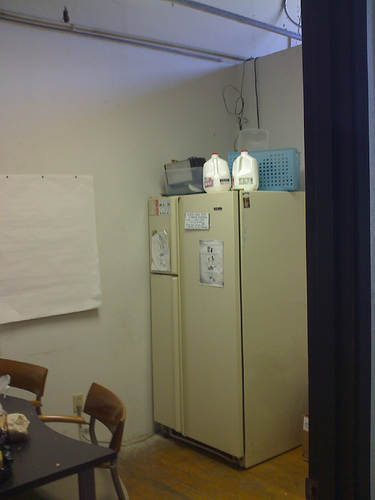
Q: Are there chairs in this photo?
A: Yes, there is a chair.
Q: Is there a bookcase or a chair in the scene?
A: Yes, there is a chair.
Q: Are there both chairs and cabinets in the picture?
A: No, there is a chair but no cabinets.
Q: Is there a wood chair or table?
A: Yes, there is a wood chair.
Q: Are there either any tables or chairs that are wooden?
A: Yes, the chair is wooden.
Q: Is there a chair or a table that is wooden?
A: Yes, the chair is wooden.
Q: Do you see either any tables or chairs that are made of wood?
A: Yes, the chair is made of wood.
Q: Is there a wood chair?
A: Yes, there is a chair that is made of wood.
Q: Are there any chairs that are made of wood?
A: Yes, there is a chair that is made of wood.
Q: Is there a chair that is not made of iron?
A: Yes, there is a chair that is made of wood.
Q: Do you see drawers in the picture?
A: No, there are no drawers.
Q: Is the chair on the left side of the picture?
A: Yes, the chair is on the left of the image.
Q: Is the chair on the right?
A: No, the chair is on the left of the image.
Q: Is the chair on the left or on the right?
A: The chair is on the left of the image.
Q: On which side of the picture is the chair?
A: The chair is on the left of the image.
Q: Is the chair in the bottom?
A: Yes, the chair is in the bottom of the image.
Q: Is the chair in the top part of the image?
A: No, the chair is in the bottom of the image.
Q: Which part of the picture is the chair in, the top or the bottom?
A: The chair is in the bottom of the image.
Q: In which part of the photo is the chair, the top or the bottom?
A: The chair is in the bottom of the image.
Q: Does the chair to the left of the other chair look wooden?
A: Yes, the chair is wooden.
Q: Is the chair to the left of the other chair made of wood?
A: Yes, the chair is made of wood.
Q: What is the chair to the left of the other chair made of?
A: The chair is made of wood.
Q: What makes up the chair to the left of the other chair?
A: The chair is made of wood.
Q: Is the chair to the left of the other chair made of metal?
A: No, the chair is made of wood.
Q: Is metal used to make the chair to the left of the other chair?
A: No, the chair is made of wood.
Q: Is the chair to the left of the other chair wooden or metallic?
A: The chair is wooden.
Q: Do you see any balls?
A: No, there are no balls.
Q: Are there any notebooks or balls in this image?
A: No, there are no balls or notebooks.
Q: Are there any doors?
A: Yes, there is a door.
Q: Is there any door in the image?
A: Yes, there is a door.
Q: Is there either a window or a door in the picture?
A: Yes, there is a door.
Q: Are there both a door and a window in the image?
A: No, there is a door but no windows.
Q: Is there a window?
A: No, there are no windows.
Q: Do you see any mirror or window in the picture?
A: No, there are no windows or mirrors.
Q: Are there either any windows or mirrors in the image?
A: No, there are no windows or mirrors.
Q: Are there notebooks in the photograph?
A: No, there are no notebooks.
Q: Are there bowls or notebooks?
A: No, there are no notebooks or bowls.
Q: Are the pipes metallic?
A: Yes, the pipes are metallic.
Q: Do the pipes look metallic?
A: Yes, the pipes are metallic.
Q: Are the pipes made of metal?
A: Yes, the pipes are made of metal.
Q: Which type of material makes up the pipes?
A: The pipes are made of metal.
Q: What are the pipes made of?
A: The pipes are made of metal.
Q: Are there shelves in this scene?
A: No, there are no shelves.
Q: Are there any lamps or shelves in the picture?
A: No, there are no shelves or lamps.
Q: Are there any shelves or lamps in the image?
A: No, there are no shelves or lamps.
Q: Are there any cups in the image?
A: No, there are no cups.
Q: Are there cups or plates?
A: No, there are no cups or plates.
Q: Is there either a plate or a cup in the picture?
A: No, there are no cups or plates.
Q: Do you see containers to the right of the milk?
A: Yes, there is a container to the right of the milk.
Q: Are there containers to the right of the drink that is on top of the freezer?
A: Yes, there is a container to the right of the milk.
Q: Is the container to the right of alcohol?
A: No, the container is to the right of the milk.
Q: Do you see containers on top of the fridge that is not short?
A: Yes, there is a container on top of the fridge.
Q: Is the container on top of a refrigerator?
A: Yes, the container is on top of a refrigerator.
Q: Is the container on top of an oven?
A: No, the container is on top of a refrigerator.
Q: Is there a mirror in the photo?
A: No, there are no mirrors.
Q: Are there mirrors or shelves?
A: No, there are no mirrors or shelves.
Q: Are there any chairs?
A: Yes, there is a chair.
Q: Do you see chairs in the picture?
A: Yes, there is a chair.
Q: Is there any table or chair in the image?
A: Yes, there is a chair.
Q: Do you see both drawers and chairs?
A: No, there is a chair but no drawers.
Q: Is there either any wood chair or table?
A: Yes, there is a wood chair.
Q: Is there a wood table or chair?
A: Yes, there is a wood chair.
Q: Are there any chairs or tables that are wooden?
A: Yes, the chair is wooden.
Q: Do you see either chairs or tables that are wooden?
A: Yes, the chair is wooden.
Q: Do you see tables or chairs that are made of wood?
A: Yes, the chair is made of wood.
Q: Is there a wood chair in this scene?
A: Yes, there is a wood chair.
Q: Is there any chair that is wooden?
A: Yes, there is a chair that is wooden.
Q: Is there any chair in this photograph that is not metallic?
A: Yes, there is a wooden chair.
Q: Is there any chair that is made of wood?
A: Yes, there is a chair that is made of wood.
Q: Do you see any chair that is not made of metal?
A: Yes, there is a chair that is made of wood.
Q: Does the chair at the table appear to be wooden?
A: Yes, the chair is wooden.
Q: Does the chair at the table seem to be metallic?
A: No, the chair is wooden.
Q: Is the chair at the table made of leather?
A: No, the chair is made of wood.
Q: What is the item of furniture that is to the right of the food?
A: The piece of furniture is a chair.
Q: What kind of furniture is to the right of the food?
A: The piece of furniture is a chair.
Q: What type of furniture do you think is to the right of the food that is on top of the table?
A: The piece of furniture is a chair.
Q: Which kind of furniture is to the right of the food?
A: The piece of furniture is a chair.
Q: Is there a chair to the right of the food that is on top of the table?
A: Yes, there is a chair to the right of the food.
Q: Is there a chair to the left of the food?
A: No, the chair is to the right of the food.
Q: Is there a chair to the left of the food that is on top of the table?
A: No, the chair is to the right of the food.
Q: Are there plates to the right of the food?
A: No, there is a chair to the right of the food.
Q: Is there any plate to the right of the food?
A: No, there is a chair to the right of the food.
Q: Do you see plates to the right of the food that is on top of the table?
A: No, there is a chair to the right of the food.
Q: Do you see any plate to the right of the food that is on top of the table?
A: No, there is a chair to the right of the food.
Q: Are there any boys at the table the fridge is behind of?
A: No, there is a chair at the table.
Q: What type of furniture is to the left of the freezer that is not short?
A: The piece of furniture is a chair.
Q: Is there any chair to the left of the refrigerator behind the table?
A: Yes, there is a chair to the left of the refrigerator.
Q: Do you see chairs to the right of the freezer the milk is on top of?
A: No, the chair is to the left of the refrigerator.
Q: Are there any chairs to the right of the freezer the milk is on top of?
A: No, the chair is to the left of the refrigerator.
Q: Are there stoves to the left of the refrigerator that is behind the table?
A: No, there is a chair to the left of the freezer.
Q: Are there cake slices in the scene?
A: No, there are no cake slices.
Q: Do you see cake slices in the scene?
A: No, there are no cake slices.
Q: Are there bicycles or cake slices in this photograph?
A: No, there are no cake slices or bicycles.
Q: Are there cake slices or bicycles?
A: No, there are no cake slices or bicycles.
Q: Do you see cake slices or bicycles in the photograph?
A: No, there are no cake slices or bicycles.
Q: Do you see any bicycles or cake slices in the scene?
A: No, there are no cake slices or bicycles.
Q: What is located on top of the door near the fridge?
A: The paper is on top of the door.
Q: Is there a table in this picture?
A: Yes, there is a table.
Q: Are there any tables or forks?
A: Yes, there is a table.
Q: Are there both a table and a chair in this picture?
A: Yes, there are both a table and a chair.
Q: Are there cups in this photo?
A: No, there are no cups.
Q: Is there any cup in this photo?
A: No, there are no cups.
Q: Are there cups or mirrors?
A: No, there are no cups or mirrors.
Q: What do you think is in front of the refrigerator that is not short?
A: The table is in front of the fridge.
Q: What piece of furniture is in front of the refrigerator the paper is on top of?
A: The piece of furniture is a table.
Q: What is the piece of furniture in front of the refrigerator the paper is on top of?
A: The piece of furniture is a table.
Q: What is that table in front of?
A: The table is in front of the fridge.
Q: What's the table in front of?
A: The table is in front of the fridge.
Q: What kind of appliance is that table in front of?
A: The table is in front of the refrigerator.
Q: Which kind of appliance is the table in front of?
A: The table is in front of the refrigerator.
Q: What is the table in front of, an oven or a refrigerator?
A: The table is in front of a refrigerator.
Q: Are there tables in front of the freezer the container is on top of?
A: Yes, there is a table in front of the freezer.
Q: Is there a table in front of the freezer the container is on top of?
A: Yes, there is a table in front of the freezer.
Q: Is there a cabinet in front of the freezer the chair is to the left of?
A: No, there is a table in front of the refrigerator.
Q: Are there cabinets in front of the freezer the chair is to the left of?
A: No, there is a table in front of the refrigerator.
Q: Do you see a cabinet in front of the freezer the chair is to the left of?
A: No, there is a table in front of the refrigerator.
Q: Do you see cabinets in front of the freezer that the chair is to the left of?
A: No, there is a table in front of the refrigerator.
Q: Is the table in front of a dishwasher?
A: No, the table is in front of a refrigerator.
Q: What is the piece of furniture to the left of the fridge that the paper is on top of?
A: The piece of furniture is a table.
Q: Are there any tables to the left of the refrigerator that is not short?
A: Yes, there is a table to the left of the refrigerator.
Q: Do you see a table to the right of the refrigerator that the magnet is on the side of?
A: No, the table is to the left of the fridge.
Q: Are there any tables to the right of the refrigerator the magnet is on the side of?
A: No, the table is to the left of the fridge.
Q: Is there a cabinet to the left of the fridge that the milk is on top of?
A: No, there is a table to the left of the freezer.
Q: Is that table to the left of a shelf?
A: No, the table is to the left of the fridge.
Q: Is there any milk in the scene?
A: Yes, there is milk.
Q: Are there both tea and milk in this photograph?
A: No, there is milk but no tea.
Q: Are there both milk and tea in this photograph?
A: No, there is milk but no tea.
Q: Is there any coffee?
A: No, there is no coffee.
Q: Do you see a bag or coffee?
A: No, there are no coffee or bags.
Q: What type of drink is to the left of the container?
A: The drink is milk.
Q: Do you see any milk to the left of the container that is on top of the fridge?
A: Yes, there is milk to the left of the container.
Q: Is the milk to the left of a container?
A: Yes, the milk is to the left of a container.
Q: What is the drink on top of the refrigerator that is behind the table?
A: The drink is milk.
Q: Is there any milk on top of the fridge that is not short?
A: Yes, there is milk on top of the refrigerator.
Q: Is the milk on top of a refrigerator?
A: Yes, the milk is on top of a refrigerator.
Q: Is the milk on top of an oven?
A: No, the milk is on top of a refrigerator.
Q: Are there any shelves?
A: No, there are no shelves.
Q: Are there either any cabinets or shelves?
A: No, there are no shelves or cabinets.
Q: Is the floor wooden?
A: Yes, the floor is wooden.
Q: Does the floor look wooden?
A: Yes, the floor is wooden.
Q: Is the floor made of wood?
A: Yes, the floor is made of wood.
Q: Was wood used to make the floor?
A: Yes, the floor is made of wood.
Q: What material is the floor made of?
A: The floor is made of wood.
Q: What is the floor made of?
A: The floor is made of wood.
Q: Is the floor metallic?
A: No, the floor is wooden.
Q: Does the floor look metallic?
A: No, the floor is wooden.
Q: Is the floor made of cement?
A: No, the floor is made of wood.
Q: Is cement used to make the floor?
A: No, the floor is made of wood.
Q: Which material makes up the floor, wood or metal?
A: The floor is made of wood.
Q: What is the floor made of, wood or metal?
A: The floor is made of wood.